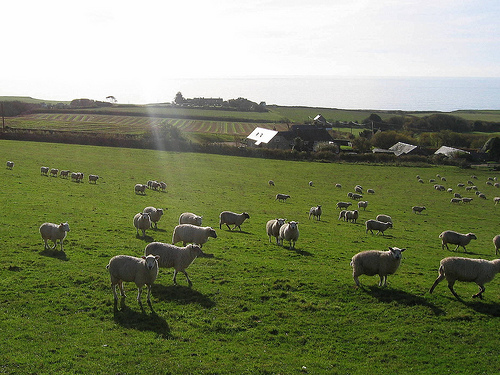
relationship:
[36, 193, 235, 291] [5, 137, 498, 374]
sheep in pasture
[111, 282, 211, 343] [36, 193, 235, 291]
shadow of sheep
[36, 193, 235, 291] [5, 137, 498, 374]
sheep on pasture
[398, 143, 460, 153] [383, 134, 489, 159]
roofs of buildings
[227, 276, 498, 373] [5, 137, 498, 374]
grass on pasture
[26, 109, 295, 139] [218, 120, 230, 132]
field containing crop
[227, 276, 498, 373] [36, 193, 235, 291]
grass beside sheep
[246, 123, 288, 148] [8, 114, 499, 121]
building in background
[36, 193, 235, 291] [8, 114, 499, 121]
sheep in background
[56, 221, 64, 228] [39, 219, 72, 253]
ear of sheep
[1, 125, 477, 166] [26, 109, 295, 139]
border of field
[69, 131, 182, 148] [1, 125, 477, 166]
shrubbery on border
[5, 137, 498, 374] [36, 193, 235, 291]
pasture of sheep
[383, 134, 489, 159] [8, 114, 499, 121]
buildings in background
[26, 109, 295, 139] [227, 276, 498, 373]
field of grass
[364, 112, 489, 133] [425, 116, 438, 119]
trees with leaves